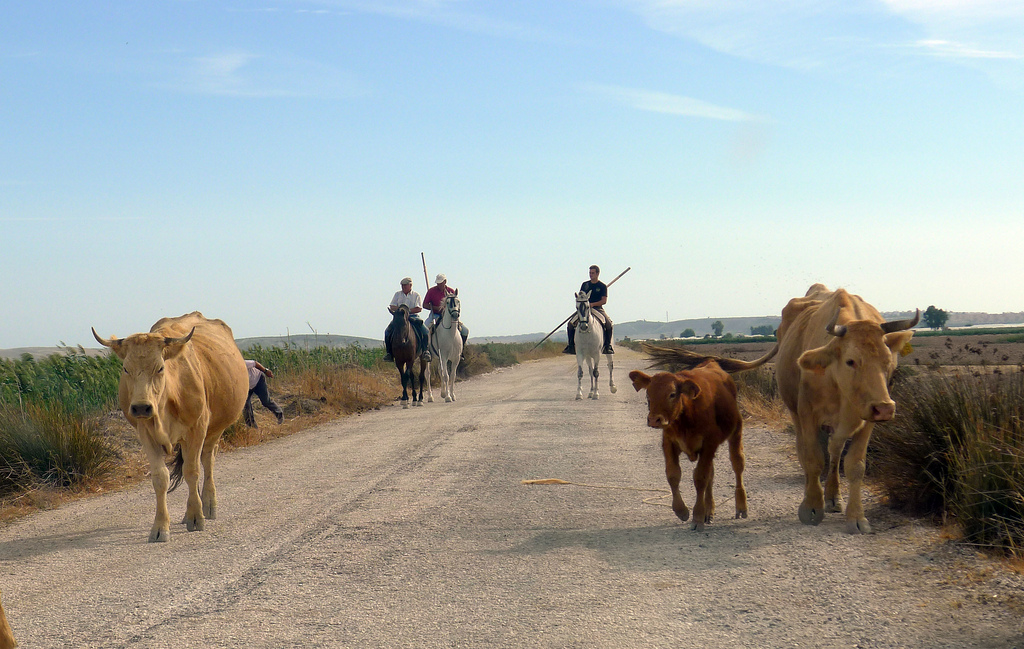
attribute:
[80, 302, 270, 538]
cow — brown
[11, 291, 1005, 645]
road — dirt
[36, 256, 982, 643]
road — dirt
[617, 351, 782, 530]
cow — brown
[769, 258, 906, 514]
cow — brown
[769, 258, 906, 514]
road — dirt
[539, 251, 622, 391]
road — dirt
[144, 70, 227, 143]
clouds — white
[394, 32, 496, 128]
clouds — white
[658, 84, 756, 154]
clouds — white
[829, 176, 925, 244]
clouds — white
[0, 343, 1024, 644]
road — dirt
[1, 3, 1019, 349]
sky — blue